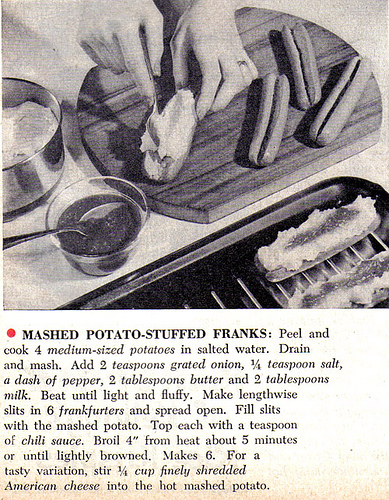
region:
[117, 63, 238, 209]
Making franks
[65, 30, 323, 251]
Cooking in the kitchen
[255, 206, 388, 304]
Mash potatoes in the hotdogs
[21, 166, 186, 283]
Sauce in the dish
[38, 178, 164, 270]
Spoon in the dish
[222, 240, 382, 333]
Hot dogs on the tray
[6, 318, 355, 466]
Recipe for mashed potato stuffed franks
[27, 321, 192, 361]
Mash potatoes and hot dogs.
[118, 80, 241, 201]
Preparing food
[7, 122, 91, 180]
A pot on the counter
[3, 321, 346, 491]
recipe written under picture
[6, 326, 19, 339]
red dot at start of recipe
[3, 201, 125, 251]
spoon in bowl of black stuff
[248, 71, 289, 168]
split hot dog on cutting board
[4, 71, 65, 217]
metal pan with white sauce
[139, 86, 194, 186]
hot dog being stuffed with potatoes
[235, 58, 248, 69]
small ring on left hand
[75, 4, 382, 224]
oblong wooden cutting board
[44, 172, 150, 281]
clear dish full of black substance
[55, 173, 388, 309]
stuffed hot dogs on baking sheet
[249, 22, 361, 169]
hot dogs on a cutting board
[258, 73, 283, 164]
a slit in a hot dog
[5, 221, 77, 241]
the handle of a spoon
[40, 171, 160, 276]
a glass bowl of sauce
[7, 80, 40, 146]
mashed potato in a pot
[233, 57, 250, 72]
a ring on a finger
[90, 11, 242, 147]
hand holding a hot dog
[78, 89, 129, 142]
a cutting board on a table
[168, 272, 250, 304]
a metal rack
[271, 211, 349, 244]
mashed potato on top of a hot dog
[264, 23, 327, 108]
a hot dog cut in half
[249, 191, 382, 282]
a hot dog stuffed with mashed potatoes ready to go into the oven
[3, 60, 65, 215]
a pot of mashed potatoes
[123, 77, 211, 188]
a woman stuffing the hot dog with mash potatoes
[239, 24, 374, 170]
three hot dogs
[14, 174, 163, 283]
a teaspoon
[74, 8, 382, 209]
a wooden cutting board with hot dogs on it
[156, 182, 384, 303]
a broiler pan with hot dogs on it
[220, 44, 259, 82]
a wedding ring on the woman's finger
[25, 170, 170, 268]
a cup of spices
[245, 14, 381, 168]
Three hot dogs on a kitchen board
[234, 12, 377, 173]
Hot dogs are cut in two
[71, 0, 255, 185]
Two hands putting sauce to a hot dog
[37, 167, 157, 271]
Bowl with sauce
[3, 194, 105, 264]
Spoon in a bowl of sauce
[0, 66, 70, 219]
Pot with solid white sauce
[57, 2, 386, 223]
Kitchen board is made of wood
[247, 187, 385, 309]
Hot dogs with sauce on a grill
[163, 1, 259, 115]
Ring on a left hand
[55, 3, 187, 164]
Right hand putting sauce on a hot dog